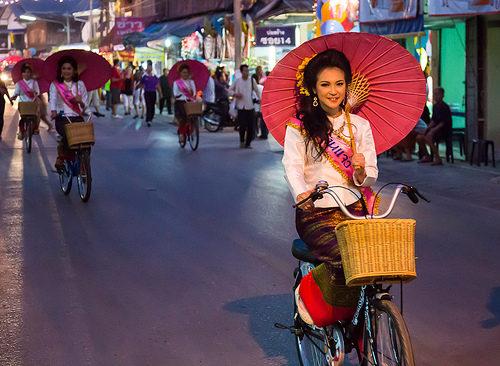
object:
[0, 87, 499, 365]
ground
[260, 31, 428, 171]
umbrella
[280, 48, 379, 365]
person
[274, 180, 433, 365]
bike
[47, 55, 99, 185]
people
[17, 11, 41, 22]
street lamp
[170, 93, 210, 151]
bikes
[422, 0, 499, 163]
building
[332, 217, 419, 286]
basket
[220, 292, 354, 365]
shadow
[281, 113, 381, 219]
sash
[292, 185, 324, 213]
handlebar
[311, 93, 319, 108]
earrings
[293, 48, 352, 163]
hair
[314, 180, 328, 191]
bell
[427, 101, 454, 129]
shirt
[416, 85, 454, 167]
person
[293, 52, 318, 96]
flowers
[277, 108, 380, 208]
shirt